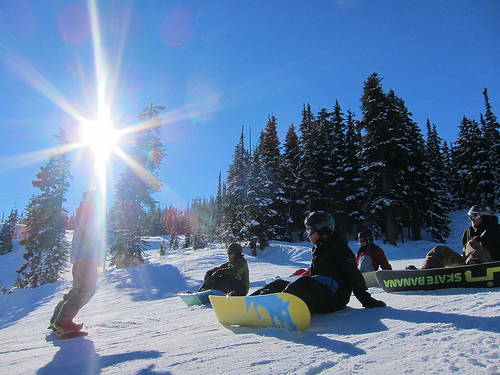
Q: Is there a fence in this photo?
A: No, there are no fences.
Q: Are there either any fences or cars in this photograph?
A: No, there are no fences or cars.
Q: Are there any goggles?
A: Yes, there are goggles.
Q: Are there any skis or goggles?
A: Yes, there are goggles.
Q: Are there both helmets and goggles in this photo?
A: Yes, there are both goggles and a helmet.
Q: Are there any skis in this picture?
A: No, there are no skis.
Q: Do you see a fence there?
A: No, there are no fences.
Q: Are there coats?
A: Yes, there is a coat.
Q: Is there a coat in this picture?
A: Yes, there is a coat.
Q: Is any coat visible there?
A: Yes, there is a coat.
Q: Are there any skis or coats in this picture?
A: Yes, there is a coat.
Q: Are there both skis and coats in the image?
A: No, there is a coat but no skis.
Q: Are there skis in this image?
A: No, there are no skis.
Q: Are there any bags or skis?
A: No, there are no skis or bags.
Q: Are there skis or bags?
A: No, there are no skis or bags.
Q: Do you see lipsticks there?
A: No, there are no lipsticks.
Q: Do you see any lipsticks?
A: No, there are no lipsticks.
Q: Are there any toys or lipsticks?
A: No, there are no lipsticks or toys.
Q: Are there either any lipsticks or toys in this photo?
A: No, there are no lipsticks or toys.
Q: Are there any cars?
A: No, there are no cars.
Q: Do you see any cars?
A: No, there are no cars.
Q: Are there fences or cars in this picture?
A: No, there are no cars or fences.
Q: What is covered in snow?
A: The tree is covered in snow.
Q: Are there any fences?
A: No, there are no fences.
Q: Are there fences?
A: No, there are no fences.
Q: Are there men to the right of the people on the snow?
A: Yes, there is a man to the right of the people.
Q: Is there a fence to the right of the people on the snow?
A: No, there is a man to the right of the people.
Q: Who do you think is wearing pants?
A: The man is wearing pants.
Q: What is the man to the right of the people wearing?
A: The man is wearing trousers.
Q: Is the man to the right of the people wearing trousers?
A: Yes, the man is wearing trousers.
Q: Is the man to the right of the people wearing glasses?
A: No, the man is wearing trousers.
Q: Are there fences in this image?
A: No, there are no fences.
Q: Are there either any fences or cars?
A: No, there are no fences or cars.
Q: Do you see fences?
A: No, there are no fences.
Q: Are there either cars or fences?
A: No, there are no fences or cars.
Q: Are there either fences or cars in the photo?
A: No, there are no fences or cars.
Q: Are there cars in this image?
A: No, there are no cars.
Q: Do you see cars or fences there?
A: No, there are no cars or fences.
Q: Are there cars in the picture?
A: No, there are no cars.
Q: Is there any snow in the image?
A: Yes, there is snow.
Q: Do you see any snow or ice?
A: Yes, there is snow.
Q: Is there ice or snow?
A: Yes, there is snow.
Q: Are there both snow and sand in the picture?
A: No, there is snow but no sand.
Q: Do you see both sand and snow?
A: No, there is snow but no sand.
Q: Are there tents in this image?
A: No, there are no tents.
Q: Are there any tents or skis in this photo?
A: No, there are no tents or skis.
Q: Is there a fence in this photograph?
A: No, there are no fences.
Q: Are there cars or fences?
A: No, there are no fences or cars.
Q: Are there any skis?
A: No, there are no skis.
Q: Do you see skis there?
A: No, there are no skis.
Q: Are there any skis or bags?
A: No, there are no skis or bags.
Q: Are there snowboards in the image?
A: Yes, there is a snowboard.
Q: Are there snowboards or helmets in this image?
A: Yes, there is a snowboard.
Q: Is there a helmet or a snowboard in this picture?
A: Yes, there is a snowboard.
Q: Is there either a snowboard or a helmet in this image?
A: Yes, there is a snowboard.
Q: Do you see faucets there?
A: No, there are no faucets.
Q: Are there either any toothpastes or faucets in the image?
A: No, there are no faucets or toothpastes.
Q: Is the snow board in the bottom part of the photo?
A: Yes, the snow board is in the bottom of the image.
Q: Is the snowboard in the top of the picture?
A: No, the snowboard is in the bottom of the image.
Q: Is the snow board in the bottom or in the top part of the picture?
A: The snow board is in the bottom of the image.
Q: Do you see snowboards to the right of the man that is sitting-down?
A: Yes, there is a snowboard to the right of the man.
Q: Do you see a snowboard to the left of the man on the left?
A: No, the snowboard is to the right of the man.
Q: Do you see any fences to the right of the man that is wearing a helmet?
A: No, there is a snowboard to the right of the man.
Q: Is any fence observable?
A: No, there are no fences.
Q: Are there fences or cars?
A: No, there are no fences or cars.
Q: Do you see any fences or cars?
A: No, there are no fences or cars.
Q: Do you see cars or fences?
A: No, there are no fences or cars.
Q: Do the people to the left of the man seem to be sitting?
A: Yes, the people are sitting.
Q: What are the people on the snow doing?
A: The people are sitting.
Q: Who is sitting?
A: The people are sitting.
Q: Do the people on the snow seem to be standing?
A: No, the people are sitting.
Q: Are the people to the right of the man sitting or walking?
A: The people are sitting.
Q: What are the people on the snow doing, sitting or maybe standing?
A: The people are sitting.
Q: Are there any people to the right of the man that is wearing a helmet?
A: Yes, there are people to the right of the man.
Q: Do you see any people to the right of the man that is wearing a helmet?
A: Yes, there are people to the right of the man.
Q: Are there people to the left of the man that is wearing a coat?
A: No, the people are to the right of the man.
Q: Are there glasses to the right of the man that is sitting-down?
A: No, there are people to the right of the man.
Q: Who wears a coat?
A: The man wears a coat.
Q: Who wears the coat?
A: The man wears a coat.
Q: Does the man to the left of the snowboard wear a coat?
A: Yes, the man wears a coat.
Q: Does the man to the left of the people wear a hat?
A: No, the man wears a coat.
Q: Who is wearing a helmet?
A: The man is wearing a helmet.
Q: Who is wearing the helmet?
A: The man is wearing a helmet.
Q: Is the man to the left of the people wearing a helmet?
A: Yes, the man is wearing a helmet.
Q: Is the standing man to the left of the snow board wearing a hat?
A: No, the man is wearing a helmet.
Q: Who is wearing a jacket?
A: The man is wearing a jacket.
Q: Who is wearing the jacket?
A: The man is wearing a jacket.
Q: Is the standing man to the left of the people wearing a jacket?
A: Yes, the man is wearing a jacket.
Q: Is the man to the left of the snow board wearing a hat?
A: No, the man is wearing a jacket.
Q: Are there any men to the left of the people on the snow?
A: Yes, there is a man to the left of the people.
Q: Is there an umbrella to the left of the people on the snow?
A: No, there is a man to the left of the people.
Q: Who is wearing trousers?
A: The man is wearing trousers.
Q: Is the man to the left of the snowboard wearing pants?
A: Yes, the man is wearing pants.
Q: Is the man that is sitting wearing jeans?
A: No, the man is wearing pants.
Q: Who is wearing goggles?
A: The man is wearing goggles.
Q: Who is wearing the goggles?
A: The man is wearing goggles.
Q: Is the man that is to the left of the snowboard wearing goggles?
A: Yes, the man is wearing goggles.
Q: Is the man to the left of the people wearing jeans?
A: No, the man is wearing goggles.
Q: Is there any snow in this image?
A: Yes, there is snow.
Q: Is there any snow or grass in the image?
A: Yes, there is snow.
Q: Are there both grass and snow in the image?
A: No, there is snow but no grass.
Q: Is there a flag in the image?
A: No, there are no flags.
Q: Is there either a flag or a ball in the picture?
A: No, there are no flags or balls.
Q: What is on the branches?
A: The snow is on the branches.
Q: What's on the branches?
A: The snow is on the branches.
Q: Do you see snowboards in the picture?
A: Yes, there is a snowboard.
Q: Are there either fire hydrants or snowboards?
A: Yes, there is a snowboard.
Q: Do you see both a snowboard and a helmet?
A: Yes, there are both a snowboard and a helmet.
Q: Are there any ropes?
A: No, there are no ropes.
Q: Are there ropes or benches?
A: No, there are no ropes or benches.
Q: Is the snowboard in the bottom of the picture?
A: Yes, the snowboard is in the bottom of the image.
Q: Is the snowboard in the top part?
A: No, the snowboard is in the bottom of the image.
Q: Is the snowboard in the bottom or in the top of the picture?
A: The snowboard is in the bottom of the image.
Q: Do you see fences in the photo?
A: No, there are no fences.